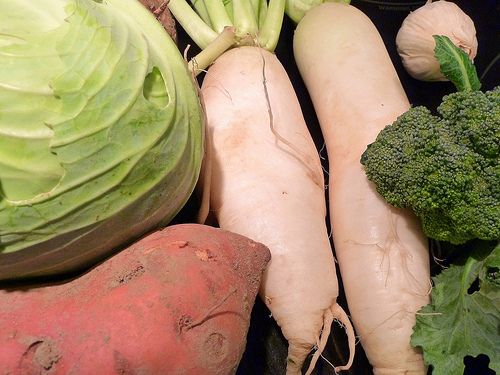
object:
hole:
[143, 66, 170, 109]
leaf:
[1, 1, 207, 279]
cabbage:
[0, 1, 206, 288]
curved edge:
[0, 0, 79, 205]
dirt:
[32, 341, 60, 370]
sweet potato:
[1, 222, 270, 374]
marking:
[204, 333, 228, 361]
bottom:
[259, 256, 356, 375]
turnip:
[201, 48, 357, 374]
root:
[285, 341, 314, 374]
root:
[304, 308, 334, 374]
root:
[332, 303, 357, 373]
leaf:
[434, 35, 480, 92]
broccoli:
[361, 85, 499, 245]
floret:
[438, 86, 499, 154]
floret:
[357, 106, 473, 213]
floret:
[412, 145, 498, 246]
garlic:
[395, 1, 477, 85]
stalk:
[166, 1, 217, 46]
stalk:
[205, 1, 232, 34]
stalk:
[233, 1, 258, 38]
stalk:
[258, 0, 287, 52]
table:
[0, 0, 499, 375]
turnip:
[292, 3, 434, 374]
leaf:
[406, 245, 498, 374]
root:
[185, 45, 213, 224]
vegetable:
[142, 1, 178, 43]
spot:
[108, 264, 145, 289]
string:
[259, 46, 325, 188]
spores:
[361, 85, 499, 247]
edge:
[179, 222, 270, 373]